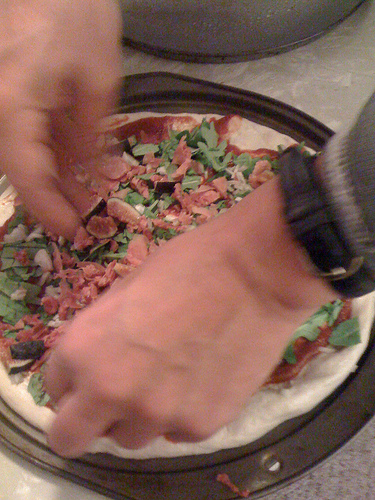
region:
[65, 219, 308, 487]
hand of the person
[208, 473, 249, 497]
a small of paper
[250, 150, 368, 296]
a black watch to hand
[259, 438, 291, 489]
a small hole on plate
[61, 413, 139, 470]
fingers of the hand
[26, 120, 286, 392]
beautiful view of leafs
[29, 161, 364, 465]
a man taking leafs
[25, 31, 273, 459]
hands of a person taking leafs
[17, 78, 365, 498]
a round plate with leafs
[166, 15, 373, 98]
a part of round plate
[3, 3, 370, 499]
two hands making a pizza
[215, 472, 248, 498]
one of the pizza toppings laying on the pan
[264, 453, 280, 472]
small circular hole in the pan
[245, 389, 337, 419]
white uncooked crust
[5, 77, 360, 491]
uncooked pizza sitting on a pan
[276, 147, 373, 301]
leather wristwatch around the wrist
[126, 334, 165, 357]
vein on the hand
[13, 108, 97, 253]
fingers touching the pizza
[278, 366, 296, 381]
glob of red sauce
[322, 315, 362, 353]
green leaf on the pizza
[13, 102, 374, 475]
the plate is black and round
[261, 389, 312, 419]
the uncooked dough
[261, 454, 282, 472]
the hole in the pan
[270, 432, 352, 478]
the metal pizza pan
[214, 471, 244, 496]
the piece of food on the metal pan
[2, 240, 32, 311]
the green toppings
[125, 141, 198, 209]
the toppings on the pizza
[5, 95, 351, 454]
the whole uncooked pizza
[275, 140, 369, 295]
the black strap on the left wrist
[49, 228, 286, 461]
the blurred left hand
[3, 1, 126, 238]
the blurred right hand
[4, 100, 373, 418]
the homemade pizza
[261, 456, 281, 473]
the hole in the pizza pan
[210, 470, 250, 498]
the small piece of food on the pizza pan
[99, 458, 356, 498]
the metal pizza pan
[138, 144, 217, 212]
the fresh toppings on the pizza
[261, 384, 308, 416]
the raw pizza dough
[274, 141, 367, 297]
the watch on the wrist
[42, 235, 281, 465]
the left hand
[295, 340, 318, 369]
the sauce on the pizza